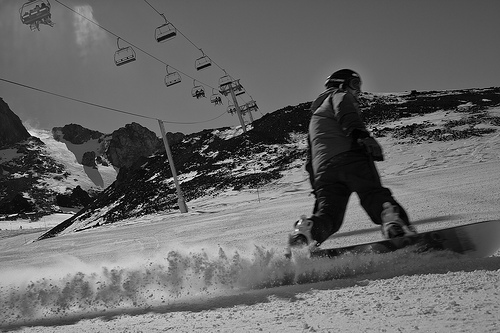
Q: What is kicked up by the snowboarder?
A: Snow.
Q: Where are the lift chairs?
A: On wires.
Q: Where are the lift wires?
A: Above the ski slope.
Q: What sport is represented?
A: Snowboarding.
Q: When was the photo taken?
A: Winter.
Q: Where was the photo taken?
A: Mountains.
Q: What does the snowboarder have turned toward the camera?
A: Back.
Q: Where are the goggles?
A: On snowboarder.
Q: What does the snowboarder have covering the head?
A: Helmet.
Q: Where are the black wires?
A: Ski lift.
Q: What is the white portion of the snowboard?
A: Bindings.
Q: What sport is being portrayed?
A: Snowboarding.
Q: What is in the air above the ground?
A: Skylift.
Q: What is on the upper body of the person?
A: Jacket.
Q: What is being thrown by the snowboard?
A: Snow.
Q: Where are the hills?
A: Background.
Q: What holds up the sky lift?
A: Poles.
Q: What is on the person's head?
A: Helmet.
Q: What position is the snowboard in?
A: Sideways.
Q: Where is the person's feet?
A: Attached to the snowboard.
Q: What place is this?
A: A ski mountain.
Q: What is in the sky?
A: Ski chairs.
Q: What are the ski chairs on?
A: Wires.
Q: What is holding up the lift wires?
A: Lift poles.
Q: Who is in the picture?
A: A snowboarder.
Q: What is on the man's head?
A: A helmet.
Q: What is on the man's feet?
A: A snowboard.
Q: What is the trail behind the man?
A: Snow.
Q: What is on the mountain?
A: Snow.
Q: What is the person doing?
A: Snowboarding.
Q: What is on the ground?
A: Snow.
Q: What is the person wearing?
A: A helmet.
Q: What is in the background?
A: Mountain.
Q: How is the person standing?
A: On the snowboard.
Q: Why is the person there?
A: To snowboard.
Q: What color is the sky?
A: Grey.